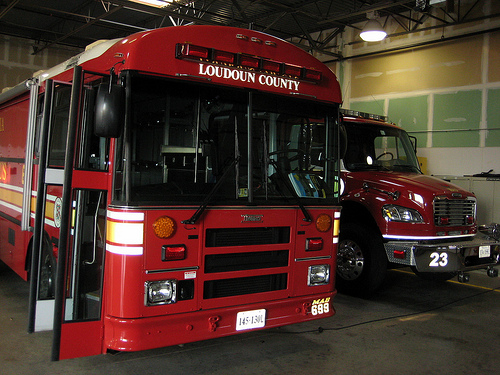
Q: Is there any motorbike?
A: No, there are no motorcycles.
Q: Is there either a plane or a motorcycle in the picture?
A: No, there are no motorcycles or airplanes.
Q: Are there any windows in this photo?
A: Yes, there is a window.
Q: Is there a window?
A: Yes, there is a window.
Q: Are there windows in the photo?
A: Yes, there is a window.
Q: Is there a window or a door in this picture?
A: Yes, there is a window.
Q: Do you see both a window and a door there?
A: Yes, there are both a window and a door.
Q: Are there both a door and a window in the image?
A: Yes, there are both a window and a door.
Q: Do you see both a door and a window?
A: Yes, there are both a window and a door.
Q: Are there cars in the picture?
A: No, there are no cars.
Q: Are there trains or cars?
A: No, there are no cars or trains.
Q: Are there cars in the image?
A: No, there are no cars.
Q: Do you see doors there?
A: Yes, there is a door.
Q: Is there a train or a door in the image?
A: Yes, there is a door.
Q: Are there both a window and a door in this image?
A: Yes, there are both a door and a window.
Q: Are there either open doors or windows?
A: Yes, there is an open door.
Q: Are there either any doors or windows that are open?
A: Yes, the door is open.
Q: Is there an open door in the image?
A: Yes, there is an open door.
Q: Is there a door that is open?
A: Yes, there is a door that is open.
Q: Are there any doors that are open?
A: Yes, there is a door that is open.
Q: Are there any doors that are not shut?
A: Yes, there is a open door.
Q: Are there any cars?
A: No, there are no cars.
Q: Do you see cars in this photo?
A: No, there are no cars.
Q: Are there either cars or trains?
A: No, there are no cars or trains.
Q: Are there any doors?
A: Yes, there is a door.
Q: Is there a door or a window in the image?
A: Yes, there is a door.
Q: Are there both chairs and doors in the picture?
A: No, there is a door but no chairs.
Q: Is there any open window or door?
A: Yes, there is an open door.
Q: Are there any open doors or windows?
A: Yes, there is an open door.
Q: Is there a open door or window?
A: Yes, there is an open door.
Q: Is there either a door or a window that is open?
A: Yes, the door is open.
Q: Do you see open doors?
A: Yes, there is an open door.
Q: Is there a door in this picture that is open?
A: Yes, there is a door that is open.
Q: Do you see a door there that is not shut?
A: Yes, there is a open door.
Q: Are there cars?
A: No, there are no cars.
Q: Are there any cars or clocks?
A: No, there are no cars or clocks.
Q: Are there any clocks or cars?
A: No, there are no cars or clocks.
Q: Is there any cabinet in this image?
A: No, there are no cabinets.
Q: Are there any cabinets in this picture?
A: No, there are no cabinets.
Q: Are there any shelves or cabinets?
A: No, there are no cabinets or shelves.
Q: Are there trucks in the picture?
A: Yes, there is a truck.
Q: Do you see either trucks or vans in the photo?
A: Yes, there is a truck.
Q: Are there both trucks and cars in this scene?
A: No, there is a truck but no cars.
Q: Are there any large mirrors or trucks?
A: Yes, there is a large truck.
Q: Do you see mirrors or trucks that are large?
A: Yes, the truck is large.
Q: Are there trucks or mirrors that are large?
A: Yes, the truck is large.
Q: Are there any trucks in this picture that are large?
A: Yes, there is a large truck.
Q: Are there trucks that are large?
A: Yes, there is a truck that is large.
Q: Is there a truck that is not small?
A: Yes, there is a large truck.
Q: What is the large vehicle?
A: The vehicle is a truck.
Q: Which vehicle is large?
A: The vehicle is a truck.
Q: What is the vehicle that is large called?
A: The vehicle is a truck.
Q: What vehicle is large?
A: The vehicle is a truck.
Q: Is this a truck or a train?
A: This is a truck.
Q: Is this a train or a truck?
A: This is a truck.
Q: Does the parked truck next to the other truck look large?
A: Yes, the truck is large.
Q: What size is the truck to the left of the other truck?
A: The truck is large.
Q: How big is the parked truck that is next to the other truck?
A: The truck is large.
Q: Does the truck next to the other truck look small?
A: No, the truck is large.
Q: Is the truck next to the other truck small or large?
A: The truck is large.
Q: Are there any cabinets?
A: No, there are no cabinets.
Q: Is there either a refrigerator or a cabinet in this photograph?
A: No, there are no cabinets or refrigerators.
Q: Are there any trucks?
A: Yes, there is a truck.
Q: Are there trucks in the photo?
A: Yes, there is a truck.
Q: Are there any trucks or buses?
A: Yes, there is a truck.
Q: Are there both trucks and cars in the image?
A: No, there is a truck but no cars.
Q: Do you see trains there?
A: No, there are no trains.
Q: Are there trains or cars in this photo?
A: No, there are no trains or cars.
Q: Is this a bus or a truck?
A: This is a truck.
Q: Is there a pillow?
A: No, there are no pillows.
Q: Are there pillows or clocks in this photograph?
A: No, there are no pillows or clocks.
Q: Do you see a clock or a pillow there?
A: No, there are no pillows or clocks.